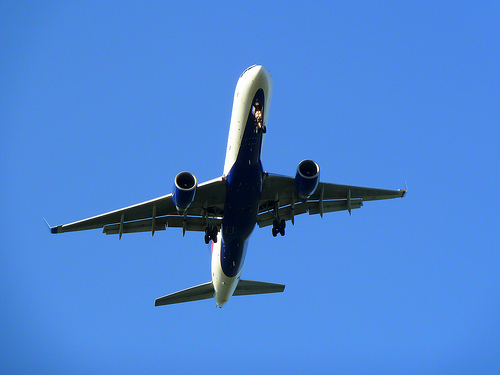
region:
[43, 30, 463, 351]
underside of plane in flight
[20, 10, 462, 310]
plane flying through clear blue sky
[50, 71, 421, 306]
darker underside of white plane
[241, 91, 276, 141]
extended front black wheels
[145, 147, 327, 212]
cylinders of engines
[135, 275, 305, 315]
flat and horizontal tail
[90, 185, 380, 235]
rectangular panels attached to wings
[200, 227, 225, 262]
a short red stripe on top of plane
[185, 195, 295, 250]
rear wheels appearing below the wings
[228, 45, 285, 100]
pointy nose of plane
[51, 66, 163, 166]
one plane in the sky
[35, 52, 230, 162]
the sky is clear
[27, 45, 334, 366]
the plane is flying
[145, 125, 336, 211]
the engines are blue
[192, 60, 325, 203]
the plane is white and blue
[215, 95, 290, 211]
the plane has wheels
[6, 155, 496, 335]
the plane has wings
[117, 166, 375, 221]
two engines on the plane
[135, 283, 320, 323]
the plane has tail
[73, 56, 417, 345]
the plane is in the sky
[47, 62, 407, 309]
an airplane flying in the sky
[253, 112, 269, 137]
front landing gear on the airplane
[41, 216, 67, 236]
left wing tip on the airplane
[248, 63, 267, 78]
nose of the airplane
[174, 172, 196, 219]
engine on left side of airplane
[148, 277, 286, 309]
tail of the airplane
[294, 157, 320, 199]
right engine on the airplane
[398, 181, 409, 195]
wing tip on right side of airplane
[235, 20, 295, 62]
sky in front of nose of airplane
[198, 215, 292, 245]
back landing gear on airplane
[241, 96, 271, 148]
Front landing gear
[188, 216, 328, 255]
Rear landing gear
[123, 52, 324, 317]
Brilliant blue and white color scheme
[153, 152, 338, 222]
Two jet engines for propulsion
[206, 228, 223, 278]
Red paint can be seen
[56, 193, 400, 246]
Flaps are down; making a decent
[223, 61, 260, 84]
Where the pilot and co-pilot sit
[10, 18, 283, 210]
A cloudless sky above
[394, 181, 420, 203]
Red light on plane wing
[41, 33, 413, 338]
Commerical jet plane en route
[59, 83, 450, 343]
the plane has two wings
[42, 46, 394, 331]
the airplane is climbing in the air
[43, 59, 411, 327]
the plane is full of people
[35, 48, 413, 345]
the plane has jets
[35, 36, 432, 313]
this is the bottom of the plane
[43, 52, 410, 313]
the plane's tires are still down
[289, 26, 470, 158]
the skies are blue and clear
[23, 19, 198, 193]
no clouds are in the sky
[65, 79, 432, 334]
the plane is large